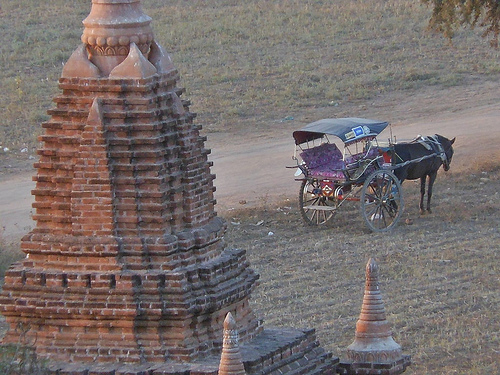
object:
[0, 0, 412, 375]
statue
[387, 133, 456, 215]
horse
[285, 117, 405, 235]
cart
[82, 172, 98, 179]
brick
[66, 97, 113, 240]
wall